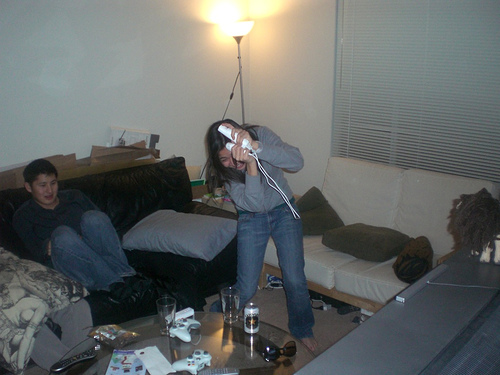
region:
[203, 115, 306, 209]
controllers are in the girl's hands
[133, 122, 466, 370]
the girl is playing a console game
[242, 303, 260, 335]
a canned beverage is on the coffee table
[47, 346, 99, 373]
a remote is on the table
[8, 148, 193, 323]
a boy is on the couch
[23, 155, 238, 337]
the couch is black leather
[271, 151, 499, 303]
a white couch has brown pillows on it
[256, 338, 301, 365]
a woman's sunglasses are on the table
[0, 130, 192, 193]
flattened boxes are behind the sofa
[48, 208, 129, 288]
the boy is wearing blue jeans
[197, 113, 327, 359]
a girl is holding a wii controller over her head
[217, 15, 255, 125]
a table lamp is on in the corner of the room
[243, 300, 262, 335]
drink can on a glass table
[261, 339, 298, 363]
sunglasses on a glass table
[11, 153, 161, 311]
a guy has his feet on the sofa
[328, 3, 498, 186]
blinds over a window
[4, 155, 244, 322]
black leather sofa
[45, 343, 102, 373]
telephone handset on the table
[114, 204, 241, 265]
white pillow on a sofa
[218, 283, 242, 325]
drinking glass on a glass table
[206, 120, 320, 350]
A girl playing the wii.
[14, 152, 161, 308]
A guy sitting on the couch.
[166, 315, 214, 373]
White xbox controllers.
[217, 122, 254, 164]
A white wii controller.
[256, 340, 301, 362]
A pair of sunglasses.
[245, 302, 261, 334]
A white and black can.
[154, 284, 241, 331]
Two clear glass cups.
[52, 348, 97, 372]
A remote controller.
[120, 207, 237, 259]
A grey pillow.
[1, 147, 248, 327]
A black sofa.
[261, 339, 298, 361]
Pair of dark black sunglasses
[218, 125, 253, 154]
White nintendo wii controller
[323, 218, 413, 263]
Square bown pillow on couch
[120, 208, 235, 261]
Long fluffy white pillow on couch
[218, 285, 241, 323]
Tall empty drinking glass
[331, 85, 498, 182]
Long white blinds over window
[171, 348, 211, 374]
White gaming controller on table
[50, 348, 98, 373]
Grey television remote control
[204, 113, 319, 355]
Girl in grey shirt playing game system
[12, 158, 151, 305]
Boy in jeans sitting on couch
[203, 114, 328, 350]
Woman playing a video game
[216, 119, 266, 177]
Game remote in woman's hands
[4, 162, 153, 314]
Boy sitting on the couch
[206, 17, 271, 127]
Lamp leaning against wall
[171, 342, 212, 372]
Game remote on table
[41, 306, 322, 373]
Circular glass coffee table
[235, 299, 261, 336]
Beer can on table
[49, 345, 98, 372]
Tv remote on table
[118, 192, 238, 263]
Gray pillow on couch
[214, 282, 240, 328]
Empty glass on table